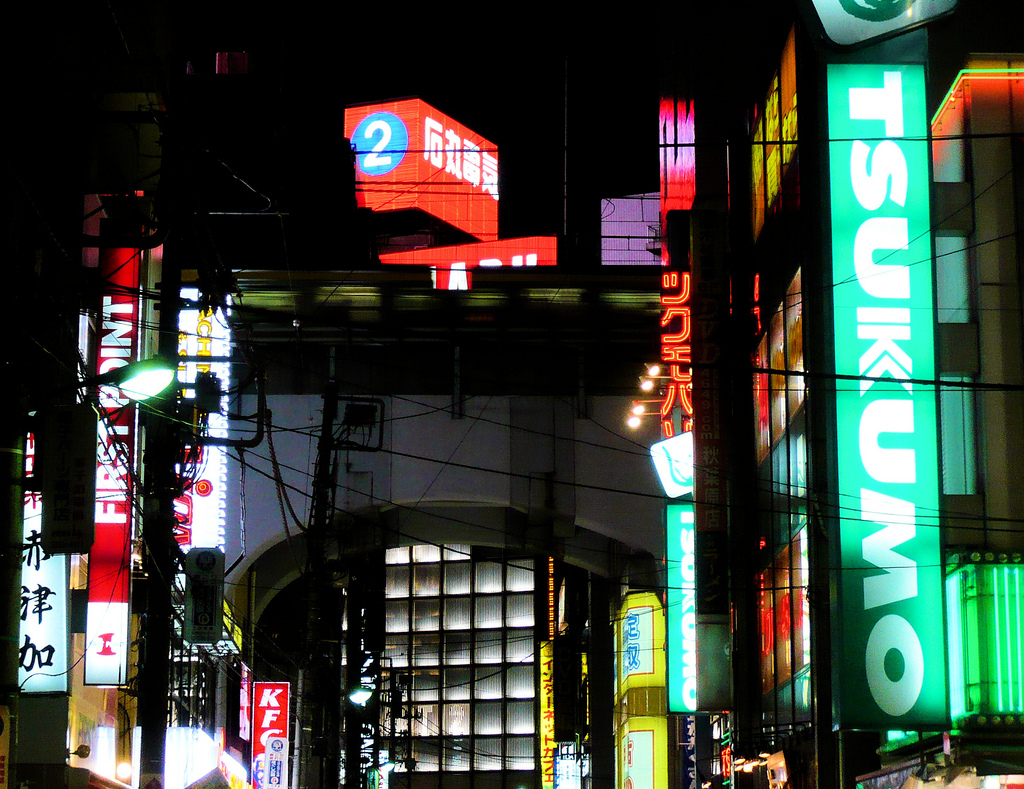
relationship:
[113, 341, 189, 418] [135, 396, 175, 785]
light mounted on pole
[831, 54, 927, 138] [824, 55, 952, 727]
letter written on advertisement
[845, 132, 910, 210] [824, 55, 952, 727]
letter written on advertisement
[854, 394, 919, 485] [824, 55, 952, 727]
letter written on advertisement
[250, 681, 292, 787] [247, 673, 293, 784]
kfc written on advertisement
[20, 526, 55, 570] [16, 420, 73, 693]
letter written on advertisement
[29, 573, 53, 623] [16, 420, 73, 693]
letter written on advertisement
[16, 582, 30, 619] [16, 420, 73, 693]
letter written on advertisement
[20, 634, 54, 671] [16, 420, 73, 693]
chineseletters written on advertisement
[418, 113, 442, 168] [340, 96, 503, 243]
letter written on advertisement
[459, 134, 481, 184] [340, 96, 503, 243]
letter written on advertisement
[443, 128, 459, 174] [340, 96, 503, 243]
letter written on advertisement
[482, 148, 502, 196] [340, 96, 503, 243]
letter written on advertisement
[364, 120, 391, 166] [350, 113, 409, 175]
number on a ball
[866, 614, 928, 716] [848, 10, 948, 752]
lettero on an advertisement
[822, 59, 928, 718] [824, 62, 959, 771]
sign has letters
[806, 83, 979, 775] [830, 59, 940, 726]
letters on sign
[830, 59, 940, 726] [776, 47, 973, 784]
sign has number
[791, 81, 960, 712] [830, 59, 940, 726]
number on sign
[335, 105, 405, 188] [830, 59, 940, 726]
number on sign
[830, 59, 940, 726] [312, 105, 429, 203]
sign in ball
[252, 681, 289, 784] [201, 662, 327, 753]
advertisement has white text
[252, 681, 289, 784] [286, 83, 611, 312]
advertisement on top of building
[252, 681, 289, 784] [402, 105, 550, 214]
advertisement has white text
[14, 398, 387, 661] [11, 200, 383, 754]
wall on building